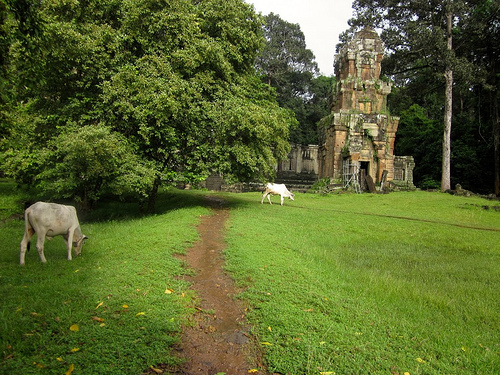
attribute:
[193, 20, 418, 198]
structure — abandoned, stone, old, amazing, decaying, aztec, buddhist, shrine, a wonder, temple, rock, tall, brick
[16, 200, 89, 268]
cow — white, grazing, looking down, eating, walking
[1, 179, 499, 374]
grass — green, short, pale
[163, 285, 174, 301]
leaf — yellow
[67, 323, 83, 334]
leaf — yellow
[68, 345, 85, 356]
leaf — yellow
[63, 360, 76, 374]
leaf — yellow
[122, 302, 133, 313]
leaf — yellow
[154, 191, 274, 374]
path — worn, dirt, thin, muddy, mud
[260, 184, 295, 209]
cow — grazing, white, distant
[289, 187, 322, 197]
step — old, stone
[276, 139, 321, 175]
building — decaying, amazing, aztec, shrine, buddhist, rock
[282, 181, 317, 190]
step — old, stone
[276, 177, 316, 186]
step — old, stone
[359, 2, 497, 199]
tree — tall, green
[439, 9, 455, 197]
trunk — tall, light colored, thin, grey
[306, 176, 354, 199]
shrubbery — low, green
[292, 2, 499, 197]
wooded area — green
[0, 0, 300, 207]
tree — enormous, large, growing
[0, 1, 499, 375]
countryside — english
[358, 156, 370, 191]
door — open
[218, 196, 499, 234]
shadow — long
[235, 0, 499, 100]
sky — overcast, cloudy, clear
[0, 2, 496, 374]
image — daytime